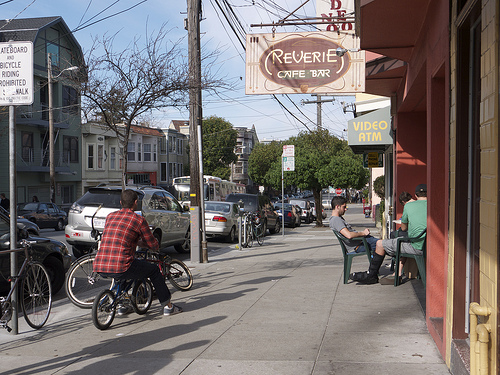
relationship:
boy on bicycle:
[95, 188, 182, 323] [90, 245, 159, 334]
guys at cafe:
[315, 186, 428, 276] [384, 50, 452, 331]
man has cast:
[350, 179, 431, 288] [345, 251, 384, 284]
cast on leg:
[345, 251, 384, 284] [351, 239, 413, 281]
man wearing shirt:
[350, 179, 431, 288] [397, 197, 429, 249]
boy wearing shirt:
[95, 188, 182, 323] [92, 208, 161, 274]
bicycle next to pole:
[1, 239, 54, 334] [5, 107, 24, 336]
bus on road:
[170, 172, 254, 203] [43, 227, 71, 242]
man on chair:
[350, 179, 431, 288] [385, 232, 429, 284]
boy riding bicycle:
[95, 188, 182, 323] [90, 245, 159, 334]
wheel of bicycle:
[92, 287, 124, 329] [90, 245, 159, 334]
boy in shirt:
[95, 188, 182, 323] [92, 208, 161, 274]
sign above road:
[247, 27, 367, 95] [43, 227, 71, 242]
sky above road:
[6, 2, 342, 135] [43, 227, 71, 242]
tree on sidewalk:
[49, 49, 172, 194] [1, 217, 437, 374]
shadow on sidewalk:
[5, 305, 227, 374] [1, 217, 437, 374]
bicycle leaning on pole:
[1, 239, 54, 334] [5, 107, 24, 336]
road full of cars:
[43, 227, 71, 242] [39, 178, 299, 265]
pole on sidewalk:
[5, 107, 24, 336] [1, 217, 437, 374]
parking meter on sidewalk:
[235, 196, 249, 249] [1, 217, 437, 374]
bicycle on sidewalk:
[1, 239, 54, 334] [1, 217, 437, 374]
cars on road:
[39, 178, 299, 265] [43, 227, 71, 242]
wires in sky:
[214, 0, 319, 132] [6, 2, 342, 135]